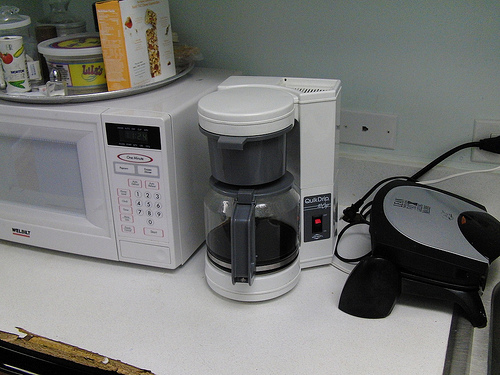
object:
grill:
[338, 180, 500, 329]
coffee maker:
[196, 75, 342, 303]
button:
[112, 152, 164, 237]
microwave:
[1, 66, 242, 270]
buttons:
[112, 152, 165, 237]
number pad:
[134, 189, 163, 225]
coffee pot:
[202, 170, 302, 287]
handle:
[231, 200, 257, 286]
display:
[105, 122, 162, 150]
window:
[0, 136, 88, 217]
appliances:
[0, 67, 500, 330]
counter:
[0, 182, 455, 374]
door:
[0, 107, 120, 261]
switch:
[311, 213, 323, 234]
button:
[155, 210, 163, 219]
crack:
[0, 326, 153, 374]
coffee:
[206, 215, 297, 275]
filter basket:
[197, 123, 295, 186]